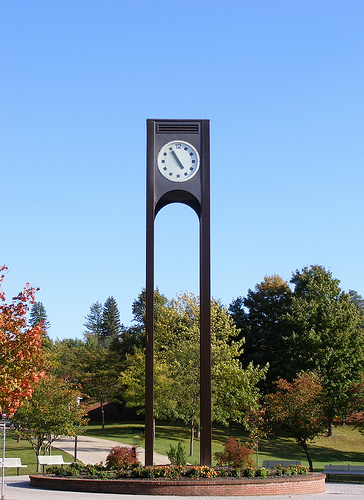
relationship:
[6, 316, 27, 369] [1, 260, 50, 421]
leaves on tree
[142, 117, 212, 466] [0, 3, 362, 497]
clock in park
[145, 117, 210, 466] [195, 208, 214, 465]
clock on pole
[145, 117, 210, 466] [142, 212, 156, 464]
clock on pole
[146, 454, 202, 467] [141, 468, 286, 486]
flowers hanging on wall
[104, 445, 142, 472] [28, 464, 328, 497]
bush near bed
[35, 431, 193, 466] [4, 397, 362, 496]
pathway in park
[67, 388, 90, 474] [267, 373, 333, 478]
light behind tree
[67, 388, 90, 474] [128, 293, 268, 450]
light behind tree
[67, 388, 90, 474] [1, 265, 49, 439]
light behind tree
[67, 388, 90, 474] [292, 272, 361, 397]
light behind tree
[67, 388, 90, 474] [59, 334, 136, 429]
light behind tree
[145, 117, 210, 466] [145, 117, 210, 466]
clock on clock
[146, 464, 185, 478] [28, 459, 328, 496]
flowers in bed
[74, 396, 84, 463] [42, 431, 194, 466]
light on pathway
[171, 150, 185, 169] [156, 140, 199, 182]
clock hand on clock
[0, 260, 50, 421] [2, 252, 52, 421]
tree lose leaves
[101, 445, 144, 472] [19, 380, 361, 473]
bush in background